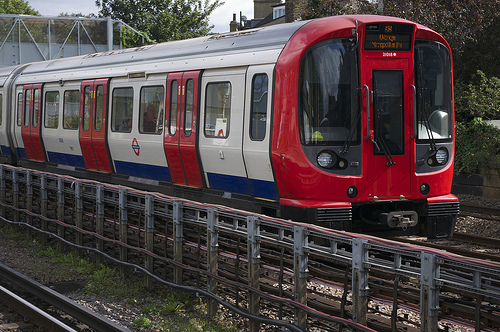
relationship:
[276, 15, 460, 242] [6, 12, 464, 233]
front of train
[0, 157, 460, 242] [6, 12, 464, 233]
bottom of train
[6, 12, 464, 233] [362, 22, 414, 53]
train has led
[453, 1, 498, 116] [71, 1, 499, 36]
tree in back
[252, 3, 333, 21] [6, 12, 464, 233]
building behind train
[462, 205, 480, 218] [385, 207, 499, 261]
part of track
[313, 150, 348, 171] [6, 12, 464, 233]
headlight on train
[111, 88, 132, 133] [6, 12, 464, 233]
window on train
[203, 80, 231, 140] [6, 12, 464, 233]
window on train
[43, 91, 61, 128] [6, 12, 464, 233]
window on train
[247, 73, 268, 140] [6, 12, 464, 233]
window on train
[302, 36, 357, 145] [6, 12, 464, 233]
window on train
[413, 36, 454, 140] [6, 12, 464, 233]
window on train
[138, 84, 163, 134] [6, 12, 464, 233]
window on train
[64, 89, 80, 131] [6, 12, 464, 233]
window on train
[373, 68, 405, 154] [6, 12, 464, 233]
windshield on train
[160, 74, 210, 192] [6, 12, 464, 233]
door of train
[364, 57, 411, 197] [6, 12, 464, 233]
door of train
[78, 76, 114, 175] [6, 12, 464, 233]
door of train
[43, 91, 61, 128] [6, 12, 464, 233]
window of train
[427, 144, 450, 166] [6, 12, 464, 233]
headlight of train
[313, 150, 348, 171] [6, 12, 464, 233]
headlight of train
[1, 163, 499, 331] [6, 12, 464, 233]
fence along train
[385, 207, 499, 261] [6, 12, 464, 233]
track for train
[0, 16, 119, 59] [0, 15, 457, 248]
barrier of subway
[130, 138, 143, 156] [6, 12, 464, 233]
logo on train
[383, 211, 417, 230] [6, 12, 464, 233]
towhook on train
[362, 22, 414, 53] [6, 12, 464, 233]
sign on train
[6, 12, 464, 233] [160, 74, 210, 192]
train has door